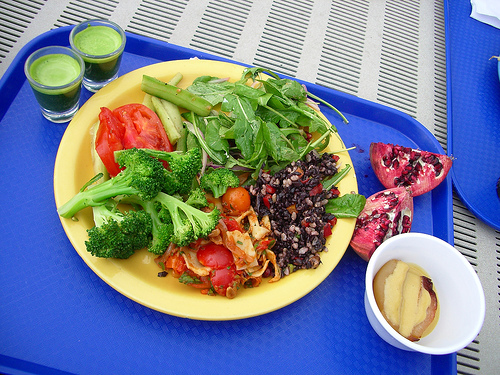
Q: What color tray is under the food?
A: Blue.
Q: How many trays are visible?
A: Two.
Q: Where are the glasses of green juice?
A: In the upper lefthand corner of the blue tray.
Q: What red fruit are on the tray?
A: Pomegranates.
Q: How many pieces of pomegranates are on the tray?
A: Two.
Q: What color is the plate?
A: Light yellow.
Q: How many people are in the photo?
A: None.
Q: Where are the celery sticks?
A: Between the tomatoes and lettuce.